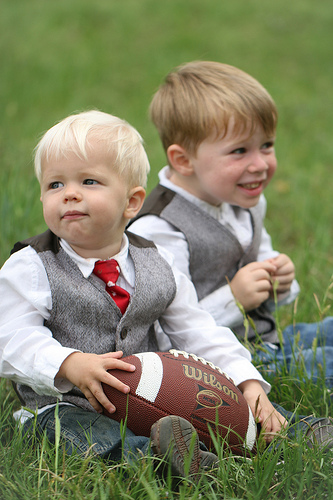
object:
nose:
[247, 152, 269, 173]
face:
[214, 125, 277, 208]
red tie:
[92, 259, 130, 313]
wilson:
[184, 364, 239, 403]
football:
[95, 350, 261, 459]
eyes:
[228, 145, 248, 158]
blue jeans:
[252, 314, 332, 388]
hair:
[33, 108, 150, 188]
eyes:
[46, 180, 64, 190]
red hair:
[148, 59, 279, 159]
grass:
[0, 0, 332, 499]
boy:
[0, 107, 333, 487]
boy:
[124, 59, 332, 384]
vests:
[10, 225, 177, 414]